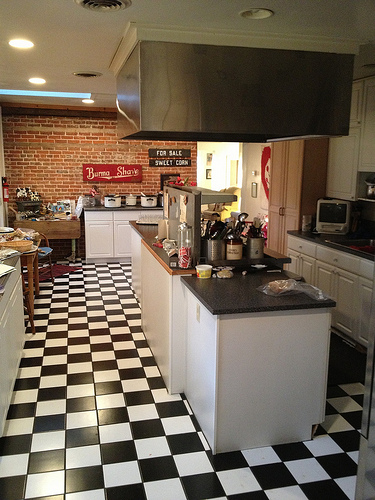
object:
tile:
[170, 449, 216, 479]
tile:
[178, 471, 229, 499]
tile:
[136, 454, 178, 483]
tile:
[204, 448, 248, 474]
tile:
[210, 464, 263, 498]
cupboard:
[267, 134, 332, 264]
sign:
[82, 164, 144, 185]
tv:
[313, 199, 350, 237]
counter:
[283, 230, 374, 265]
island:
[126, 220, 338, 458]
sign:
[146, 148, 189, 161]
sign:
[147, 158, 192, 168]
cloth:
[351, 244, 372, 252]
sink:
[324, 234, 374, 260]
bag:
[255, 278, 329, 303]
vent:
[113, 37, 359, 144]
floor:
[0, 257, 365, 499]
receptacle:
[195, 303, 200, 324]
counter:
[179, 268, 336, 316]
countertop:
[179, 269, 337, 314]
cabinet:
[180, 268, 337, 455]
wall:
[0, 114, 196, 219]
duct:
[116, 40, 357, 142]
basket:
[0, 240, 33, 252]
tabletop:
[0, 227, 40, 255]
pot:
[139, 192, 157, 208]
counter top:
[81, 202, 164, 212]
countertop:
[286, 229, 375, 263]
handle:
[333, 258, 338, 266]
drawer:
[314, 245, 362, 279]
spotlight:
[8, 37, 35, 52]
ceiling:
[0, 0, 374, 95]